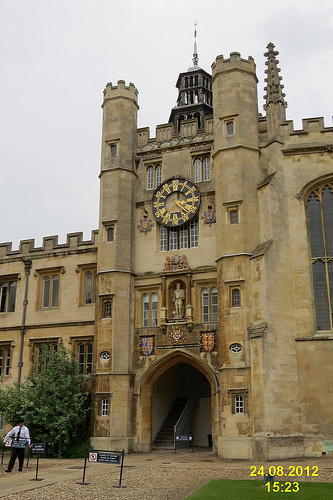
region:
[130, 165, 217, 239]
the clock is in the front of the building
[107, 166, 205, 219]
the numbers on the clock are gold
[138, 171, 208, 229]
the numbers are roman numerals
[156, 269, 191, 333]
a statue of a man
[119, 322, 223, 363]
a red and blue shield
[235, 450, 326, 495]
the time and date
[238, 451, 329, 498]
the numbers are yellow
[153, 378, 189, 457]
the stairs are dim lit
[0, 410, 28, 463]
the man is holding a sign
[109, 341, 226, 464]
an entrance to the building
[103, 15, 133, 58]
part of a cloud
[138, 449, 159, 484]
part of a floor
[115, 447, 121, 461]
part of a board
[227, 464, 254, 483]
part of a floor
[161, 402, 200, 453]
part of a stair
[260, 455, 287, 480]
partt of a date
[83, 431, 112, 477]
part of a board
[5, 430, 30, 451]
poart of a tie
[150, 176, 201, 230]
black and gold clock face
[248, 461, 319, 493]
yellow time and date stamp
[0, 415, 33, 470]
man wearing a neck tie and hat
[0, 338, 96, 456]
tree next to the building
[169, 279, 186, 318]
knight statue on the building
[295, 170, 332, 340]
huge decorative window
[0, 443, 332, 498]
gravel pebble walking path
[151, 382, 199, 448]
short concrete staircase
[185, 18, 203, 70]
decorative metal spire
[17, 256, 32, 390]
black drainage pipe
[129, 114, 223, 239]
a large outside clock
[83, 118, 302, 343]
a large clock on building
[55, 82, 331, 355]
a large clock on an old building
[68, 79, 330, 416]
an old building with clock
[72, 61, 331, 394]
an old building with large clock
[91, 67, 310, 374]
a building with outside clock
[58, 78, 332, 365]
an old building with outside clock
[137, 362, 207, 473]
a stairs on a building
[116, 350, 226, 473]
a building with stairs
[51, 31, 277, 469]
a building with windows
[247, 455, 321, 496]
yellow date and time stamp on picture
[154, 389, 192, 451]
set of stairs inside the building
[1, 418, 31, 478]
man standing behind a sign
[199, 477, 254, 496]
green grass in front of a building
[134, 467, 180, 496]
cobblestone pavement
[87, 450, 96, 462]
red and white forbidden sign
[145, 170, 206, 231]
large clock with gold Roman numerals.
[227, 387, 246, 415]
small window at bottom of building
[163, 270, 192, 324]
statue above entry way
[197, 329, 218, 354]
red and gold crest